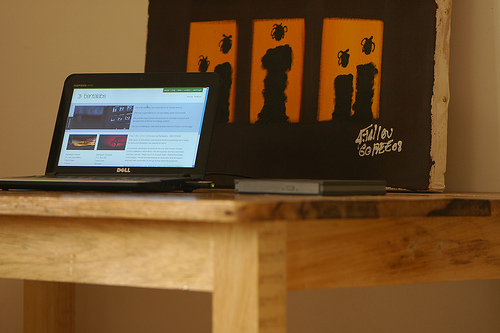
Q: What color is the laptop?
A: Black.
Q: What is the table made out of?
A: Wood.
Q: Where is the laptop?
A: On the desk.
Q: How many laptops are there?
A: One.